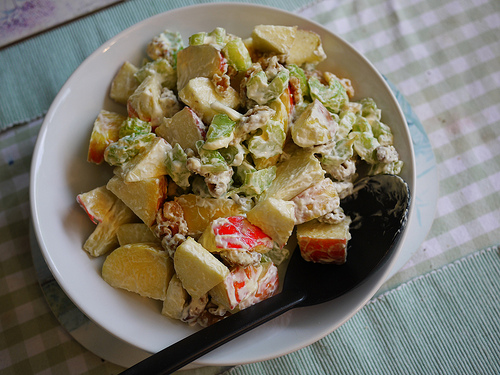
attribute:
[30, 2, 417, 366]
bowl — round, white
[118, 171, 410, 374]
spoon — black, large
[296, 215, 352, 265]
apple — sliced, red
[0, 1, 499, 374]
tablecloth — checkered, multi colored, green, white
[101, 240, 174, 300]
potato — cooked, sliced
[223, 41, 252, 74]
grape — green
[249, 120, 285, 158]
celery — green, sliced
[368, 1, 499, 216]
stripe — green, white